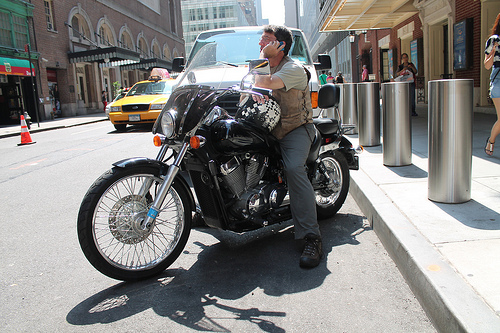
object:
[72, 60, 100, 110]
doorway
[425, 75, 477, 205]
barriers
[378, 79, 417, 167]
barriers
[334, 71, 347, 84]
people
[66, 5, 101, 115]
arch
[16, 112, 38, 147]
cone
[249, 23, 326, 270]
man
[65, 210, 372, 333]
shadow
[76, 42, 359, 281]
motorcycle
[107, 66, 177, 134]
cab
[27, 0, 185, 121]
building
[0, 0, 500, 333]
city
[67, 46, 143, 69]
awning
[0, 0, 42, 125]
building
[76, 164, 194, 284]
tire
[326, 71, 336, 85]
people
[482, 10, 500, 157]
woman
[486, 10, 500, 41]
hair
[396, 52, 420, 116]
people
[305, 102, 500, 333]
sidewalk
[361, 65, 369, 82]
people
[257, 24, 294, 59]
head